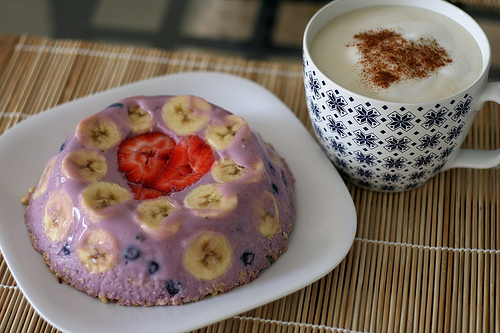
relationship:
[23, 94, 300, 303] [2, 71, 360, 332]
desert on plate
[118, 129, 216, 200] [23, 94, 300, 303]
cherry on desert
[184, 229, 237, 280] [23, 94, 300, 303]
banana on desert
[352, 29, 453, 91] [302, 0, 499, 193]
cinnamon in cup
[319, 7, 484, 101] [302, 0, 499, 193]
drink in cup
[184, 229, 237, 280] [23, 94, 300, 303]
banana in desert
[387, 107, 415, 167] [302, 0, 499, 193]
design on cup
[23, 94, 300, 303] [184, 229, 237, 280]
desert has banana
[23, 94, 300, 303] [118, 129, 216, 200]
desert has cherry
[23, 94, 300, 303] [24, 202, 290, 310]
desert has flan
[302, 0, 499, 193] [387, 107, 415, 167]
cup has design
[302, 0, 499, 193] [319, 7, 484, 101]
cup has drink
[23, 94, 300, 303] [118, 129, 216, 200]
desert has berry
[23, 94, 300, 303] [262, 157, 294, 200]
desert has blueberry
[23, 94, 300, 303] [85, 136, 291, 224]
desert has fruit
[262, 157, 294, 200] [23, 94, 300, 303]
blueberry in desert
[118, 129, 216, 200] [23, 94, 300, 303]
cherry in desert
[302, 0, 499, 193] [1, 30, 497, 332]
cup on table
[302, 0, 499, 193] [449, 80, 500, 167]
cup has handle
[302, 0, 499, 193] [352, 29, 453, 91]
cup has cinnamon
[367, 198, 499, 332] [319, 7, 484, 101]
platemat under drink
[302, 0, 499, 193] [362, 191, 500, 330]
cup on placemat